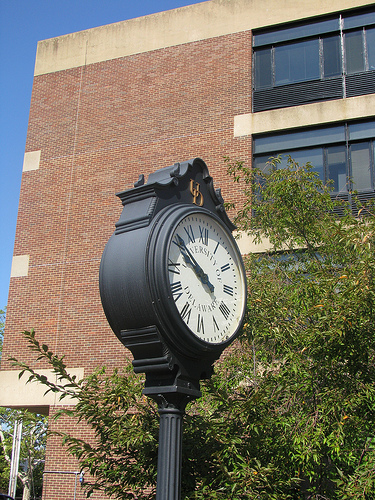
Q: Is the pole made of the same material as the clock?
A: Yes, both the pole and the clock are made of metal.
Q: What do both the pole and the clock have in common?
A: The material, both the pole and the clock are metallic.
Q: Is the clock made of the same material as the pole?
A: Yes, both the clock and the pole are made of metal.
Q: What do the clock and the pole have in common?
A: The material, both the clock and the pole are metallic.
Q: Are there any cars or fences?
A: No, there are no cars or fences.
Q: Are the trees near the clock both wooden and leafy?
A: Yes, the trees are wooden and leafy.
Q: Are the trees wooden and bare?
A: No, the trees are wooden but leafy.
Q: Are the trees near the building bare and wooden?
A: No, the trees are wooden but leafy.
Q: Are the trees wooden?
A: Yes, the trees are wooden.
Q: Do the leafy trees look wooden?
A: Yes, the trees are wooden.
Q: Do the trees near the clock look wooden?
A: Yes, the trees are wooden.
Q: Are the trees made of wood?
A: Yes, the trees are made of wood.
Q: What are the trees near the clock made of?
A: The trees are made of wood.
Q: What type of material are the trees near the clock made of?
A: The trees are made of wood.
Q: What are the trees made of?
A: The trees are made of wood.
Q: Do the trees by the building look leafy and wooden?
A: Yes, the trees are leafy and wooden.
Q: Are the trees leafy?
A: Yes, the trees are leafy.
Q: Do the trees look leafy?
A: Yes, the trees are leafy.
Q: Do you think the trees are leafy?
A: Yes, the trees are leafy.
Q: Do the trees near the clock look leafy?
A: Yes, the trees are leafy.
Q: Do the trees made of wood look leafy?
A: Yes, the trees are leafy.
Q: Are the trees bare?
A: No, the trees are leafy.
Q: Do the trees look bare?
A: No, the trees are leafy.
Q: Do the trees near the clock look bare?
A: No, the trees are leafy.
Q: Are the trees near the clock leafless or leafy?
A: The trees are leafy.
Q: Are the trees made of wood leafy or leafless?
A: The trees are leafy.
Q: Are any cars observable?
A: No, there are no cars.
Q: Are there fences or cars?
A: No, there are no cars or fences.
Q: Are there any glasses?
A: No, there are no glasses.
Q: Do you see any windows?
A: Yes, there are windows.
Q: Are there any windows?
A: Yes, there are windows.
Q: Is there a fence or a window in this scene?
A: Yes, there are windows.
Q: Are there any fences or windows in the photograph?
A: Yes, there are windows.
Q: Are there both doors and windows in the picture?
A: No, there are windows but no doors.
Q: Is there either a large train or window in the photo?
A: Yes, there are large windows.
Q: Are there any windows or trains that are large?
A: Yes, the windows are large.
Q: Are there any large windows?
A: Yes, there are large windows.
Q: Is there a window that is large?
A: Yes, there are windows that are large.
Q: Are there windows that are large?
A: Yes, there are windows that are large.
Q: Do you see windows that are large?
A: Yes, there are windows that are large.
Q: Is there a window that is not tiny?
A: Yes, there are large windows.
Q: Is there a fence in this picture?
A: No, there are no fences.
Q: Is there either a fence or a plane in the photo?
A: No, there are no fences or airplanes.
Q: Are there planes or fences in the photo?
A: No, there are no fences or planes.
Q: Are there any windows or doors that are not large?
A: No, there are windows but they are large.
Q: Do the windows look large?
A: Yes, the windows are large.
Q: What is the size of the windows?
A: The windows are large.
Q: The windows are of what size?
A: The windows are large.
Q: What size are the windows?
A: The windows are large.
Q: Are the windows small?
A: No, the windows are large.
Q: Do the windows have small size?
A: No, the windows are large.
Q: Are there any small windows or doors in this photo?
A: No, there are windows but they are large.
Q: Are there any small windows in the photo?
A: No, there are windows but they are large.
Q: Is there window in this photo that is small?
A: No, there are windows but they are large.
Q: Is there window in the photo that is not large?
A: No, there are windows but they are large.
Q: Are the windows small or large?
A: The windows are large.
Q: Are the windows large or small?
A: The windows are large.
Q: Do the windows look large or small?
A: The windows are large.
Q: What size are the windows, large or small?
A: The windows are large.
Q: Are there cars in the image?
A: No, there are no cars.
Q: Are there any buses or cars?
A: No, there are no cars or buses.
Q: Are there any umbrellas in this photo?
A: No, there are no umbrellas.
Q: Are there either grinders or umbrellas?
A: No, there are no umbrellas or grinders.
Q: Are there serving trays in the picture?
A: No, there are no serving trays.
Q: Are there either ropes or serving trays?
A: No, there are no serving trays or ropes.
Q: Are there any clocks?
A: Yes, there is a clock.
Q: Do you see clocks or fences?
A: Yes, there is a clock.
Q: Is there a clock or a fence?
A: Yes, there is a clock.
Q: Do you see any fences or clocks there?
A: Yes, there is a clock.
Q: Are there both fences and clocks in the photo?
A: No, there is a clock but no fences.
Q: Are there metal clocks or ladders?
A: Yes, there is a metal clock.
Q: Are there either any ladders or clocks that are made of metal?
A: Yes, the clock is made of metal.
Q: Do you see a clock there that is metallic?
A: Yes, there is a metal clock.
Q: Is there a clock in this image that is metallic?
A: Yes, there is a clock that is metallic.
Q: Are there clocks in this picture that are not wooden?
A: Yes, there is a metallic clock.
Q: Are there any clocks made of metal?
A: Yes, there is a clock that is made of metal.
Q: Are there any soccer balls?
A: No, there are no soccer balls.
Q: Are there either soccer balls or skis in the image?
A: No, there are no soccer balls or skis.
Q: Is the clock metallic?
A: Yes, the clock is metallic.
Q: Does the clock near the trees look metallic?
A: Yes, the clock is metallic.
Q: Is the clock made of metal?
A: Yes, the clock is made of metal.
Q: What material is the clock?
A: The clock is made of metal.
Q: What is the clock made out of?
A: The clock is made of metal.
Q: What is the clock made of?
A: The clock is made of metal.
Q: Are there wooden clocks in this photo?
A: No, there is a clock but it is metallic.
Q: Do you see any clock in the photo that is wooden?
A: No, there is a clock but it is metallic.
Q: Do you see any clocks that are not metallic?
A: No, there is a clock but it is metallic.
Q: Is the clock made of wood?
A: No, the clock is made of metal.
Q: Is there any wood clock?
A: No, there is a clock but it is made of metal.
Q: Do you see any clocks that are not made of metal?
A: No, there is a clock but it is made of metal.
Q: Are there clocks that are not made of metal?
A: No, there is a clock but it is made of metal.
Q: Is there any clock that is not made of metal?
A: No, there is a clock but it is made of metal.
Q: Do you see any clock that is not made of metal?
A: No, there is a clock but it is made of metal.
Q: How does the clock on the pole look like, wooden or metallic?
A: The clock is metallic.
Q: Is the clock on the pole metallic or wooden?
A: The clock is metallic.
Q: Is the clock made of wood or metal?
A: The clock is made of metal.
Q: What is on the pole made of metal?
A: The clock is on the pole.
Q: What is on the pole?
A: The clock is on the pole.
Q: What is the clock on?
A: The clock is on the pole.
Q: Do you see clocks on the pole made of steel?
A: Yes, there is a clock on the pole.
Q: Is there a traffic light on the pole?
A: No, there is a clock on the pole.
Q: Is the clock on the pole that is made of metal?
A: Yes, the clock is on the pole.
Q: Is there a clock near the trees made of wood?
A: Yes, there is a clock near the trees.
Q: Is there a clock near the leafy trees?
A: Yes, there is a clock near the trees.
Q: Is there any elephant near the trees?
A: No, there is a clock near the trees.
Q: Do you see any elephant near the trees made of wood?
A: No, there is a clock near the trees.